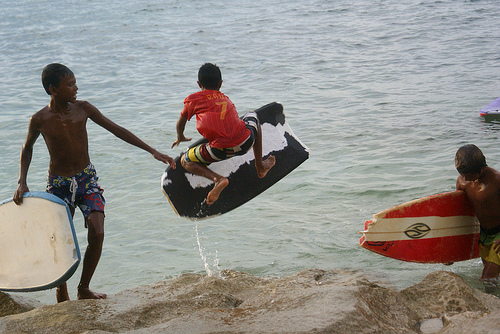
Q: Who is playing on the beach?
A: Children.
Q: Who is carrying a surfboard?
A: A young boy.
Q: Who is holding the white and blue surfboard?
A: The boy on the left.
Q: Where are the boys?
A: Near the water.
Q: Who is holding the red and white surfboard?
A: The boy on the right.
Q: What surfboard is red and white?
A: The farthest to the right.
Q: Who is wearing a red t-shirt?
A: The jumping boy.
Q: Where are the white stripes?
A: On the red surfboard.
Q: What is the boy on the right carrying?
A: A surfboard.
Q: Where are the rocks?
A: Next to the water.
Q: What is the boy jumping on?
A: A body board.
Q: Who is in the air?
A: The boy in the red shirt.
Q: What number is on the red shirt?
A: 7.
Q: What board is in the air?
A: The black one.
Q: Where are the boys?
A: At the beach.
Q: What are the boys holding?
A: Surfboards.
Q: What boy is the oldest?
A: The one on the left.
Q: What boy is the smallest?
A: The one in the air.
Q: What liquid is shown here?
A: Ocean water.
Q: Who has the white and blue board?
A: The boy on the left.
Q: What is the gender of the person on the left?
A: Male.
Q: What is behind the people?
A: Water.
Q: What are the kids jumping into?
A: The water.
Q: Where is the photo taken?
A: The beach.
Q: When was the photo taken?
A: Daytime.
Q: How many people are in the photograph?
A: Three.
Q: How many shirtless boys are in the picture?
A: Two.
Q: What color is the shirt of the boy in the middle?
A: Orange.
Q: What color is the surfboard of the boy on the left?
A: White.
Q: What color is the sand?
A: Tan.